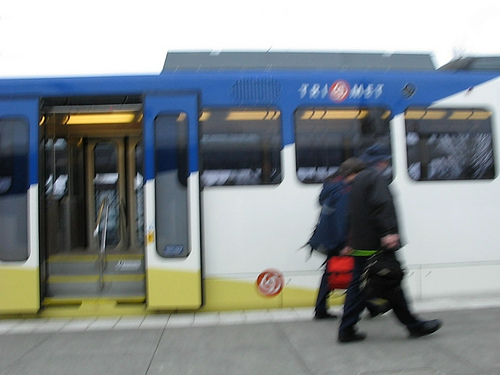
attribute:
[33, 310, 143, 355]
entryway — RAPID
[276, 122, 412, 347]
people — walking, next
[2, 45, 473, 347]
train — commuter, blue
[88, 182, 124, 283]
rail — metal, hand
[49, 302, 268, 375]
sidewalk — TRANSIT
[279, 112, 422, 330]
person — walking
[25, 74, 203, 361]
door — open, blue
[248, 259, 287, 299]
logo — met, transit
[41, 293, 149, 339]
platform — white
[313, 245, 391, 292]
bag — red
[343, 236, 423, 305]
back pack — black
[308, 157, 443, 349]
man — wearing, holding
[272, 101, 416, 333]
woman — wearing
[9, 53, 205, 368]
transit — trimet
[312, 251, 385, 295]
suitcase — red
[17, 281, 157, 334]
stairway — yellow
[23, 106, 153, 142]
lighting — covered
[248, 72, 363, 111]
background — painted